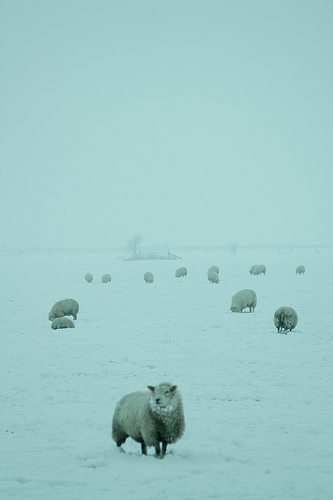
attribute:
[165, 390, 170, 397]
eye — in the picture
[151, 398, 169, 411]
nose — in the picture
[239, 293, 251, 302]
wool — gray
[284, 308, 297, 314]
wool — gray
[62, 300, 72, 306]
wool — gray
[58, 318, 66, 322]
wool — gray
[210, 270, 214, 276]
wool — gray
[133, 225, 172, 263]
tree — background.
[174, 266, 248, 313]
wool sheep — brown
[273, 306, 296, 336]
sheep — five 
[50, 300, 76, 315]
wool — thick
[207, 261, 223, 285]
sheep — eight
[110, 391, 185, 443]
wool — heavy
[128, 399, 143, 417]
wool — thick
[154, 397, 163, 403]
nose — black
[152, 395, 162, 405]
nose — black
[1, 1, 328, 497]
picture — white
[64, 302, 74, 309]
wool — brown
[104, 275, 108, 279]
wool — brown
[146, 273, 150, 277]
wool — brown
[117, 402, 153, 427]
wool — thick 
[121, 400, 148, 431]
wool — thick